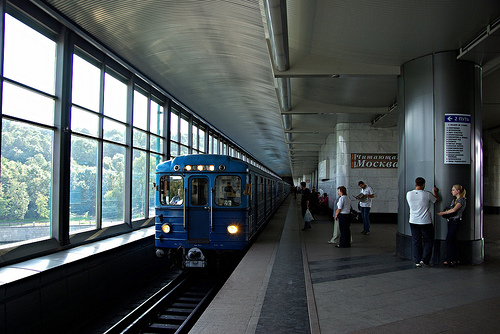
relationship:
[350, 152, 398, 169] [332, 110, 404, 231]
sign on wall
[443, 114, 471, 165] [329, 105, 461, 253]
wall sign on wall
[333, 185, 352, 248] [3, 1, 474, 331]
people standing in train station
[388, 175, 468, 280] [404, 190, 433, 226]
man wearing shirt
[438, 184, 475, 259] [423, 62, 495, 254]
lady standing against pillar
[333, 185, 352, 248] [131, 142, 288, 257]
people waiting for train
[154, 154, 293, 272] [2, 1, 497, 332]
train to an indoor area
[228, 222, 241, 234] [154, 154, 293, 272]
light of train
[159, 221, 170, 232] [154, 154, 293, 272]
light of train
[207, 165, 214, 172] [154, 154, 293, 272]
light of train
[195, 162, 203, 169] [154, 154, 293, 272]
light of train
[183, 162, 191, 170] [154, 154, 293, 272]
light of train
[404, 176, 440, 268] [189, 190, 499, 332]
man on platform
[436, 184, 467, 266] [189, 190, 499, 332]
lady on platform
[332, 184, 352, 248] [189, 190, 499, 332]
people on platform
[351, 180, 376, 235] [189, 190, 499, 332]
man on platform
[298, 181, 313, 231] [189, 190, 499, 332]
man on platform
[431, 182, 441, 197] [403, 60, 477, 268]
hand on pillar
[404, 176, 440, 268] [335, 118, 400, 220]
man touching wall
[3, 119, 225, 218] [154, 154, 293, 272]
bushes outside train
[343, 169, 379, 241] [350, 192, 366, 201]
man reading object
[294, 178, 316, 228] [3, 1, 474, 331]
man standing at train station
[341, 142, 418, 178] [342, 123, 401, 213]
sign on wall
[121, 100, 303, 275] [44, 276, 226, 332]
train on tracks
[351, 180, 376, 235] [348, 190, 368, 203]
man reading from object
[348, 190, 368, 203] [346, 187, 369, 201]
object in h hands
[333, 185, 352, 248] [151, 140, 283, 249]
people looking towards train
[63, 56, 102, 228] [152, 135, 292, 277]
window to left of train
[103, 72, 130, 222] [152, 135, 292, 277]
window to left of train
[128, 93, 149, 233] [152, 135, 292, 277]
window to left of train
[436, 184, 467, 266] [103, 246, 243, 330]
lady waiting next to tracks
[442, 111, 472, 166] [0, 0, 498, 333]
wall sign in train station